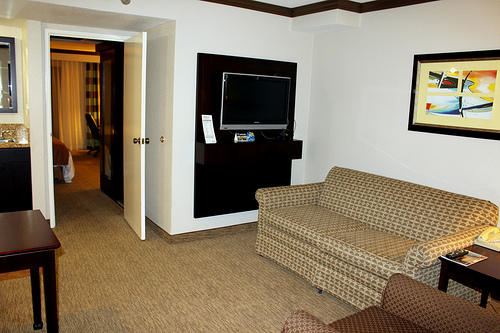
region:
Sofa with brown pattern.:
[252, 166, 495, 311]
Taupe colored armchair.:
[280, 274, 498, 332]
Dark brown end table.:
[439, 223, 498, 307]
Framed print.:
[406, 45, 498, 141]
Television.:
[221, 67, 295, 141]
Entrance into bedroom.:
[35, 25, 150, 240]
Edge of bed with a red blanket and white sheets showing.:
[51, 134, 76, 186]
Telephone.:
[474, 223, 499, 250]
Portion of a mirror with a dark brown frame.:
[0, 34, 17, 114]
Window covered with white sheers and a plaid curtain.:
[51, 49, 103, 159]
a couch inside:
[260, 138, 490, 330]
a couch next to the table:
[232, 133, 483, 313]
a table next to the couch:
[297, 148, 479, 253]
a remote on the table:
[444, 233, 499, 294]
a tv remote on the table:
[457, 233, 489, 273]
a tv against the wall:
[184, 58, 310, 159]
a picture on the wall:
[386, 26, 499, 176]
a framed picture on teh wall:
[397, 40, 499, 151]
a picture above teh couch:
[347, 22, 494, 274]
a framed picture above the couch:
[314, 20, 496, 277]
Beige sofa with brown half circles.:
[251, 165, 498, 314]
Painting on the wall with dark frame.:
[404, 48, 499, 145]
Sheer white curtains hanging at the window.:
[52, 59, 87, 151]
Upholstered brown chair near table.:
[277, 271, 495, 331]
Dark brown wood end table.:
[438, 246, 498, 308]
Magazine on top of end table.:
[440, 247, 486, 267]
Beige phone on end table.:
[474, 226, 499, 250]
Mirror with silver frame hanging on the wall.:
[0, 34, 19, 116]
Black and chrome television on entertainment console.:
[215, 68, 292, 133]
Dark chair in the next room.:
[82, 112, 103, 157]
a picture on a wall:
[393, 44, 498, 157]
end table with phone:
[426, 218, 498, 308]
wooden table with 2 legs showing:
[2, 197, 80, 328]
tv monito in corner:
[208, 60, 304, 147]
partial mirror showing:
[0, 30, 25, 116]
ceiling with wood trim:
[206, 0, 471, 21]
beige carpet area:
[90, 240, 285, 308]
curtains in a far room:
[58, 61, 108, 175]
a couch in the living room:
[251, 155, 497, 297]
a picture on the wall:
[396, 41, 499, 143]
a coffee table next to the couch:
[438, 239, 496, 311]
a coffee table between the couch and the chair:
[431, 233, 498, 315]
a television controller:
[441, 244, 473, 264]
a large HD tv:
[207, 62, 298, 151]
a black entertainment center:
[183, 40, 302, 237]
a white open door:
[38, 19, 155, 258]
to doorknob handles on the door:
[125, 125, 157, 158]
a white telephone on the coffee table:
[465, 219, 499, 259]